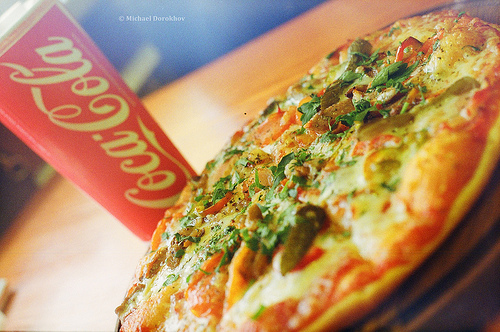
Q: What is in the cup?
A: Coca-cola.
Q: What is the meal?
A: Pizza.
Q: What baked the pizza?
A: An oven.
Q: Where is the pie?
A: On a table.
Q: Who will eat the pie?
A: The diner.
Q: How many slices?
A: At least 6.